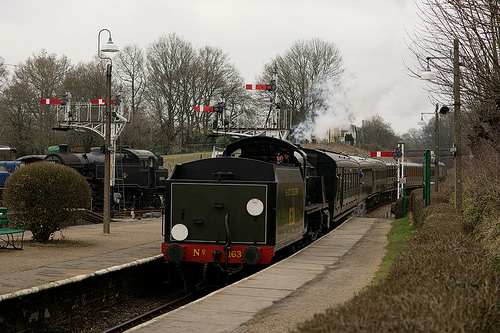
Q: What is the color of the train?
A: Black.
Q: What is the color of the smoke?
A: White.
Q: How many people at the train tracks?
A: Zero.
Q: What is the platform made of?
A: Stones and cement.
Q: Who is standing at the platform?
A: No one.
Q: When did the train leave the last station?
A: Yesterday.